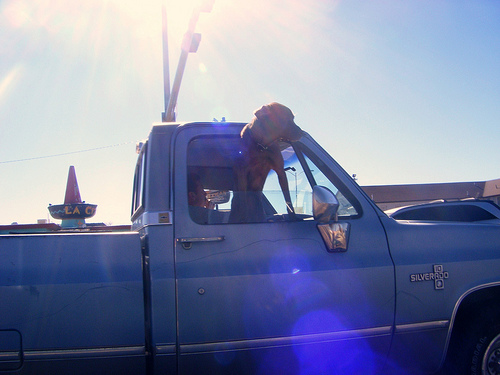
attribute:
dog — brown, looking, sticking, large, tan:
[220, 90, 308, 223]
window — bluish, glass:
[187, 118, 361, 227]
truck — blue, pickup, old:
[5, 112, 494, 362]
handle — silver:
[177, 229, 227, 244]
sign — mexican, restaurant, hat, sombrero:
[46, 162, 102, 234]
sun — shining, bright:
[38, 0, 286, 141]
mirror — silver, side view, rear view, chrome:
[308, 183, 349, 254]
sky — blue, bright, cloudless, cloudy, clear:
[3, 0, 496, 218]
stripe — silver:
[3, 317, 450, 363]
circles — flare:
[256, 238, 398, 370]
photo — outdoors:
[8, 1, 500, 362]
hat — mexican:
[47, 161, 100, 219]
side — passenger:
[3, 116, 499, 368]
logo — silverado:
[412, 258, 450, 298]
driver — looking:
[190, 167, 238, 230]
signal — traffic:
[155, 0, 221, 126]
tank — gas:
[2, 323, 23, 371]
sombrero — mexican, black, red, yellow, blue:
[47, 164, 99, 225]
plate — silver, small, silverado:
[408, 261, 451, 293]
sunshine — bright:
[1, 1, 500, 174]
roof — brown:
[371, 174, 500, 199]